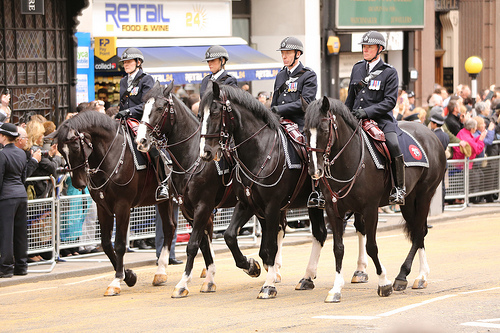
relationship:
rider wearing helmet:
[343, 27, 413, 207] [356, 28, 388, 48]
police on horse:
[117, 48, 147, 118] [132, 75, 168, 150]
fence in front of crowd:
[22, 137, 499, 271] [2, 90, 499, 204]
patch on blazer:
[363, 79, 386, 92] [364, 79, 389, 96]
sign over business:
[76, 1, 237, 38] [81, 1, 296, 128]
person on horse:
[267, 32, 328, 209] [194, 77, 371, 298]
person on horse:
[199, 45, 234, 88] [133, 79, 240, 299]